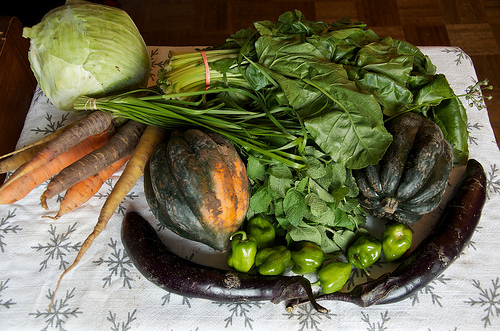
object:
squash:
[360, 112, 457, 225]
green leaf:
[261, 51, 396, 173]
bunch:
[157, 9, 471, 171]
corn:
[146, 130, 252, 253]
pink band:
[199, 51, 212, 90]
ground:
[344, 118, 381, 155]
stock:
[69, 84, 311, 176]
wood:
[396, 9, 497, 41]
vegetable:
[0, 0, 487, 309]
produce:
[2, 1, 492, 308]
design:
[33, 288, 90, 330]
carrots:
[2, 111, 112, 191]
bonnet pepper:
[227, 231, 257, 272]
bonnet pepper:
[256, 246, 293, 276]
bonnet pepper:
[316, 261, 352, 294]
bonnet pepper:
[346, 239, 382, 269]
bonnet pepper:
[382, 220, 412, 261]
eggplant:
[280, 158, 487, 315]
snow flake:
[27, 286, 82, 329]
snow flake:
[217, 297, 261, 331]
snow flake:
[467, 276, 498, 327]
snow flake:
[95, 238, 133, 291]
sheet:
[4, 45, 499, 331]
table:
[2, 44, 495, 330]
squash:
[142, 125, 251, 255]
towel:
[6, 35, 499, 330]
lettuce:
[162, 7, 444, 172]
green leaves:
[343, 63, 411, 118]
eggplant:
[120, 211, 329, 317]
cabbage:
[24, 0, 150, 111]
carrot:
[0, 126, 114, 205]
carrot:
[38, 122, 170, 312]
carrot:
[38, 155, 131, 222]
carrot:
[39, 120, 145, 211]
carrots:
[0, 144, 61, 172]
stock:
[149, 39, 241, 106]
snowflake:
[29, 219, 87, 273]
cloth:
[0, 45, 499, 330]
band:
[83, 97, 96, 111]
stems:
[72, 93, 115, 116]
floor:
[2, 1, 498, 109]